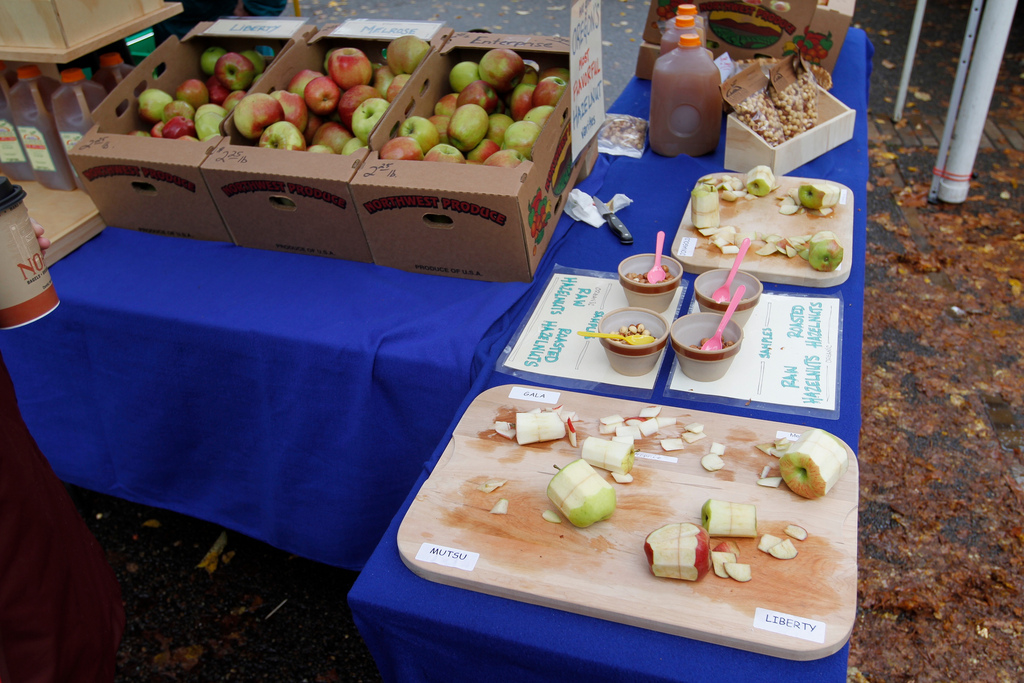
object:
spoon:
[576, 329, 659, 346]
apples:
[377, 31, 441, 80]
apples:
[345, 94, 395, 146]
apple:
[417, 137, 471, 173]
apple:
[440, 100, 494, 154]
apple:
[132, 83, 183, 123]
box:
[55, 14, 314, 254]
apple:
[207, 45, 266, 95]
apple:
[373, 128, 429, 168]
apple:
[535, 454, 623, 534]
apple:
[628, 520, 724, 594]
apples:
[766, 426, 854, 503]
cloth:
[0, 0, 877, 683]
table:
[0, 0, 878, 683]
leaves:
[894, 239, 955, 275]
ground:
[868, 0, 1023, 672]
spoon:
[698, 283, 752, 353]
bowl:
[689, 261, 769, 334]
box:
[335, 18, 612, 292]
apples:
[438, 99, 498, 155]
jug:
[643, 28, 727, 163]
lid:
[673, 29, 706, 48]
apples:
[790, 173, 849, 214]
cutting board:
[663, 160, 866, 292]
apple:
[636, 515, 722, 589]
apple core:
[501, 401, 577, 452]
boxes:
[191, 12, 452, 270]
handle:
[600, 210, 638, 246]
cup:
[0, 170, 71, 336]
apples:
[469, 43, 536, 95]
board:
[389, 375, 868, 660]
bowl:
[666, 304, 751, 388]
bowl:
[591, 301, 674, 380]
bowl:
[611, 249, 687, 320]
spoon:
[710, 235, 757, 304]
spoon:
[646, 227, 669, 286]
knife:
[589, 192, 636, 245]